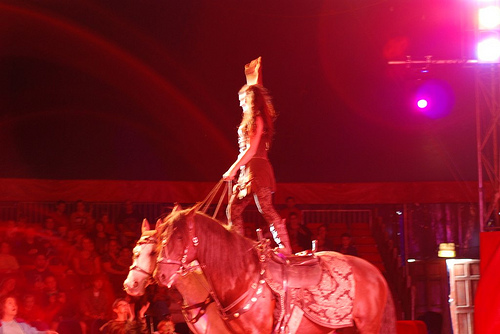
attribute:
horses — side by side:
[114, 200, 402, 328]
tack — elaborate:
[163, 233, 356, 331]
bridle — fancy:
[127, 232, 157, 282]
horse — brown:
[153, 205, 393, 328]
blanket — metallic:
[301, 250, 355, 328]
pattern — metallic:
[300, 249, 356, 329]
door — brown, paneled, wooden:
[447, 254, 480, 331]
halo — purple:
[408, 81, 455, 121]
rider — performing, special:
[219, 58, 294, 263]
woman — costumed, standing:
[217, 54, 293, 263]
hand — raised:
[250, 55, 264, 88]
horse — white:
[120, 215, 224, 332]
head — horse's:
[141, 200, 210, 293]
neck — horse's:
[188, 210, 246, 303]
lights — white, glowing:
[473, 7, 483, 69]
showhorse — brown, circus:
[118, 198, 374, 331]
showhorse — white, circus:
[120, 197, 400, 330]